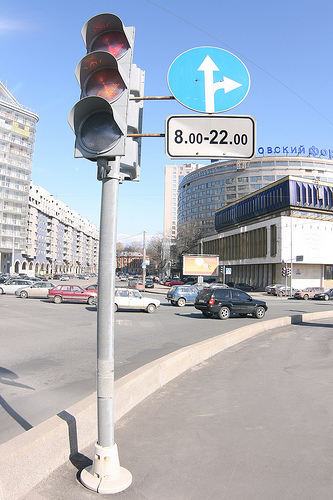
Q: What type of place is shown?
A: It is a parking lot.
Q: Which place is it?
A: It is a parking lot.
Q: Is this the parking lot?
A: Yes, it is the parking lot.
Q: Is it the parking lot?
A: Yes, it is the parking lot.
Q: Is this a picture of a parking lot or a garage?
A: It is showing a parking lot.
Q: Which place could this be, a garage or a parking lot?
A: It is a parking lot.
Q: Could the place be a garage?
A: No, it is a parking lot.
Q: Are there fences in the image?
A: No, there are no fences.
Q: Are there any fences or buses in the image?
A: No, there are no fences or buses.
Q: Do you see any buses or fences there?
A: No, there are no fences or buses.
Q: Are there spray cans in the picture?
A: No, there are no spray cans.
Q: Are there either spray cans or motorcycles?
A: No, there are no spray cans or motorcycles.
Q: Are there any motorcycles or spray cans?
A: No, there are no spray cans or motorcycles.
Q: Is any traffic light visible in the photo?
A: Yes, there is a traffic light.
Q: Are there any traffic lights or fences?
A: Yes, there is a traffic light.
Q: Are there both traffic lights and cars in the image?
A: Yes, there are both a traffic light and a car.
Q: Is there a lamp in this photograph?
A: No, there are no lamps.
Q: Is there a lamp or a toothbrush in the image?
A: No, there are no lamps or toothbrushes.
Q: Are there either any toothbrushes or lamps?
A: No, there are no lamps or toothbrushes.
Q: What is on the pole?
A: The traffic signal is on the pole.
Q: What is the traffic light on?
A: The traffic light is on the pole.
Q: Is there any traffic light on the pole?
A: Yes, there is a traffic light on the pole.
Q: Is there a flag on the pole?
A: No, there is a traffic light on the pole.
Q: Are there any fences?
A: No, there are no fences.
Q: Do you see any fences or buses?
A: No, there are no fences or buses.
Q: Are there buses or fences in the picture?
A: No, there are no fences or buses.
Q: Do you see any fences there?
A: No, there are no fences.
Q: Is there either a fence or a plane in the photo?
A: No, there are no fences or airplanes.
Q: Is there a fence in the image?
A: No, there are no fences.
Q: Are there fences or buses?
A: No, there are no fences or buses.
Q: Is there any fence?
A: No, there are no fences.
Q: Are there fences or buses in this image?
A: No, there are no fences or buses.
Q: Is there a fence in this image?
A: No, there are no fences.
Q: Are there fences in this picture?
A: No, there are no fences.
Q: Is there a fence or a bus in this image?
A: No, there are no fences or buses.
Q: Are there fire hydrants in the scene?
A: No, there are no fire hydrants.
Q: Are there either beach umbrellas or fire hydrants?
A: No, there are no fire hydrants or beach umbrellas.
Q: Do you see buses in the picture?
A: No, there are no buses.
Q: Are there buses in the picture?
A: No, there are no buses.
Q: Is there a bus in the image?
A: No, there are no buses.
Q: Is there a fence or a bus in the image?
A: No, there are no buses or fences.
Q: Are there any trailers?
A: No, there are no trailers.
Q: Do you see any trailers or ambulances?
A: No, there are no trailers or ambulances.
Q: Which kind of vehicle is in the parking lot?
A: The vehicle is a car.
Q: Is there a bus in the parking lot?
A: No, there is a car in the parking lot.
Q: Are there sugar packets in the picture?
A: No, there are no sugar packets.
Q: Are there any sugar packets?
A: No, there are no sugar packets.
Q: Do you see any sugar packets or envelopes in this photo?
A: No, there are no sugar packets or envelopes.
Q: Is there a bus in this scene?
A: No, there are no buses.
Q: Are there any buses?
A: No, there are no buses.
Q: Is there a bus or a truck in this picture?
A: No, there are no buses or trucks.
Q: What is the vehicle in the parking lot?
A: The vehicle is a car.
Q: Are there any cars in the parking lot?
A: Yes, there is a car in the parking lot.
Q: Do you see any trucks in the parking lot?
A: No, there is a car in the parking lot.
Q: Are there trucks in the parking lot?
A: No, there is a car in the parking lot.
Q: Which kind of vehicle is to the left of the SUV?
A: The vehicle is a car.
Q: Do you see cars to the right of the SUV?
A: No, the car is to the left of the SUV.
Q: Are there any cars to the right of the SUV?
A: No, the car is to the left of the SUV.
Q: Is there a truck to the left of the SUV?
A: No, there is a car to the left of the SUV.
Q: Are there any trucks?
A: No, there are no trucks.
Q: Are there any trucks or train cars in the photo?
A: No, there are no trucks or train cars.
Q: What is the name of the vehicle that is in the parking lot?
A: The vehicle is a car.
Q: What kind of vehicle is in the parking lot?
A: The vehicle is a car.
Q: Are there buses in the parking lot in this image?
A: No, there is a car in the parking lot.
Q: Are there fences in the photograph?
A: No, there are no fences.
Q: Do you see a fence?
A: No, there are no fences.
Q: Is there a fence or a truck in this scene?
A: No, there are no fences or trucks.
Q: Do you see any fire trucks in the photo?
A: No, there are no fire trucks.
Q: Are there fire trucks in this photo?
A: No, there are no fire trucks.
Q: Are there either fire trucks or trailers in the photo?
A: No, there are no fire trucks or trailers.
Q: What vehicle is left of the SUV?
A: The vehicle is a car.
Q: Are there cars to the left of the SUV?
A: Yes, there is a car to the left of the SUV.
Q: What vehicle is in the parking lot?
A: The vehicle is a car.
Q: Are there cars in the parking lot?
A: Yes, there is a car in the parking lot.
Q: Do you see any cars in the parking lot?
A: Yes, there is a car in the parking lot.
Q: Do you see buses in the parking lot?
A: No, there is a car in the parking lot.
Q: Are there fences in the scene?
A: No, there are no fences.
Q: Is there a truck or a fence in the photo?
A: No, there are no fences or trucks.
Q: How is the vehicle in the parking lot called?
A: The vehicle is a car.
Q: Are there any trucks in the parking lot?
A: No, there is a car in the parking lot.